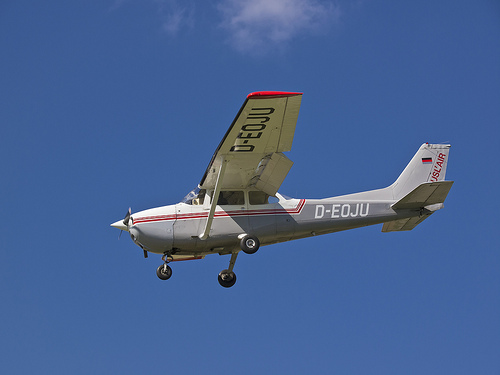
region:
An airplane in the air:
[95, 77, 466, 304]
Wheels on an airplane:
[139, 233, 271, 287]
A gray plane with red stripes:
[103, 182, 437, 242]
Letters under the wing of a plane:
[223, 100, 278, 169]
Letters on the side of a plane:
[303, 198, 375, 228]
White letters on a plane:
[310, 196, 372, 226]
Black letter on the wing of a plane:
[226, 96, 276, 158]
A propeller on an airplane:
[105, 193, 167, 257]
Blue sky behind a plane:
[48, 52, 495, 292]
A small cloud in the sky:
[123, 3, 421, 64]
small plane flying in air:
[86, 49, 484, 312]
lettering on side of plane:
[309, 201, 372, 228]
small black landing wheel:
[243, 233, 265, 253]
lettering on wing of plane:
[219, 98, 280, 170]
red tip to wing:
[248, 81, 307, 111]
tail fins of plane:
[378, 131, 456, 246]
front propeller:
[93, 198, 130, 245]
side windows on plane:
[177, 185, 289, 216]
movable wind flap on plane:
[237, 145, 299, 211]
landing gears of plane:
[136, 231, 270, 294]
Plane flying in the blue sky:
[76, 80, 471, 310]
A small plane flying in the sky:
[85, 111, 444, 312]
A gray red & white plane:
[62, 180, 455, 246]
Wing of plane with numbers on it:
[189, 62, 312, 196]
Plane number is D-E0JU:
[210, 54, 322, 169]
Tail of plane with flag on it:
[406, 132, 455, 192]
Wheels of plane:
[156, 237, 253, 290]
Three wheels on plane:
[108, 185, 283, 316]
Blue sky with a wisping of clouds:
[30, 13, 307, 127]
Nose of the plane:
[93, 183, 175, 258]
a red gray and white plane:
[94, 61, 479, 305]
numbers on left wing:
[220, 103, 273, 161]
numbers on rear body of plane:
[306, 193, 382, 234]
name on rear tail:
[408, 146, 468, 190]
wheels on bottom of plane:
[209, 223, 263, 298]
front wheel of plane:
[154, 263, 173, 283]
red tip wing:
[192, 71, 308, 181]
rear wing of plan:
[391, 176, 453, 216]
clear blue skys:
[17, 8, 224, 149]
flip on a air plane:
[259, 143, 296, 199]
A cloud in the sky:
[127, 0, 352, 59]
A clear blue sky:
[2, 3, 496, 373]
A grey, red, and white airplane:
[73, 74, 453, 294]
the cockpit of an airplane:
[183, 183, 286, 207]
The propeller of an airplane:
[112, 204, 132, 240]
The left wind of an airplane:
[197, 89, 308, 191]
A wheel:
[240, 230, 261, 257]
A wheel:
[218, 267, 237, 290]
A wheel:
[156, 260, 178, 283]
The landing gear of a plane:
[153, 235, 258, 292]